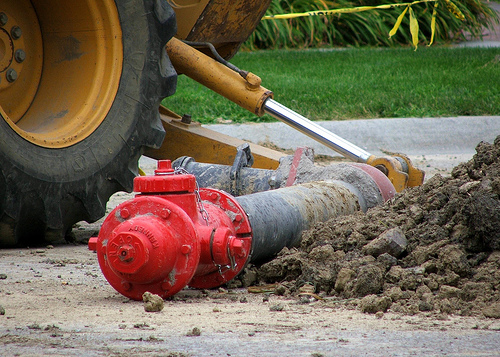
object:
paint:
[190, 63, 229, 85]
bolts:
[0, 11, 8, 27]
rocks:
[344, 264, 382, 298]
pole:
[259, 97, 370, 163]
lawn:
[161, 41, 500, 126]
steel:
[260, 97, 371, 166]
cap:
[106, 215, 178, 285]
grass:
[157, 44, 499, 124]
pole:
[233, 179, 370, 262]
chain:
[156, 167, 191, 174]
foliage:
[348, 0, 390, 49]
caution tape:
[260, 0, 444, 53]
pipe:
[183, 156, 370, 269]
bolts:
[116, 245, 133, 261]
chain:
[195, 180, 210, 226]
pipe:
[166, 156, 384, 264]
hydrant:
[88, 159, 255, 302]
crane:
[143, 27, 426, 195]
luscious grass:
[316, 50, 412, 89]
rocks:
[362, 227, 410, 258]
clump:
[361, 229, 409, 258]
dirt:
[0, 130, 499, 357]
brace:
[163, 36, 426, 192]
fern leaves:
[258, 20, 302, 52]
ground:
[1, 46, 498, 355]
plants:
[244, 0, 493, 46]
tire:
[0, 0, 178, 246]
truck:
[0, 0, 426, 247]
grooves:
[140, 2, 177, 78]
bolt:
[11, 25, 22, 39]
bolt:
[15, 49, 27, 63]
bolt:
[7, 69, 17, 83]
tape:
[258, 1, 466, 52]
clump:
[141, 291, 164, 313]